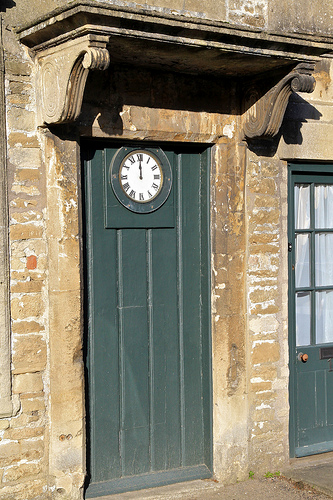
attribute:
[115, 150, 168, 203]
clock — old-fashioned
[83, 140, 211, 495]
door — old, green, shut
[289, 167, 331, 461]
door — old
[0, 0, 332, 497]
building — old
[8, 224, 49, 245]
brick — old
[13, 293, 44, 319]
brick — old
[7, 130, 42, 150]
brick — old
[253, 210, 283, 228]
brick — old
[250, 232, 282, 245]
brick — old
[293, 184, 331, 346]
curtain — white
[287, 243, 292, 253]
doorbell — black, white